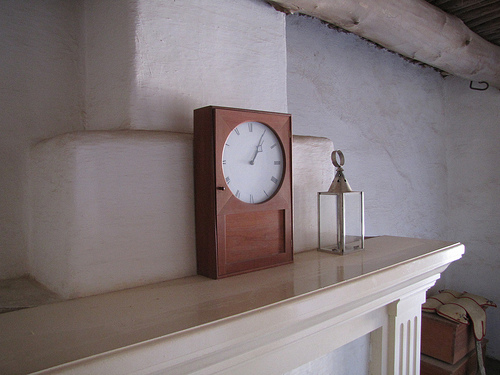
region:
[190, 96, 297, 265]
the clock sitting on the mantle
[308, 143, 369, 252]
a tiny little decoration by the clock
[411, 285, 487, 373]
some boes in the corner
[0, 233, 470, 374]
the mantle of the fireplace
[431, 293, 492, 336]
some fabric on top of the box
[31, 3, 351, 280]
a part of the chimney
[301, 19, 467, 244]
the wall of the house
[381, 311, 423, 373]
a column next to the fireplace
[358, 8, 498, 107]
a log near the ceiling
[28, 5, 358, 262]
part of the chimney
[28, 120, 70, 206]
Part of a white wall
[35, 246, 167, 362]
Part of a white wall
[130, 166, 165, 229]
Part of a white wall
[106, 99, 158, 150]
Part of a white wall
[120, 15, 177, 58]
Part of a white wall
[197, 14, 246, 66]
Part of a white wall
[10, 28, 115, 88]
Part of a white wall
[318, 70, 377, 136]
Part of a white wall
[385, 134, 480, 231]
Part of a white wall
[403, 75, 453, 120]
Part of a white wall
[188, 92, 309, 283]
a clock is white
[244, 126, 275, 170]
handles of clock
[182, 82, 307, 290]
a clock on brown frame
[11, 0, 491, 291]
a white wall behind a clock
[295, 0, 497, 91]
a log on a roof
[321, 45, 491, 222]
wall is color white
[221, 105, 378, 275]
a silver thing on side a clock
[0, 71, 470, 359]
a clock on side counter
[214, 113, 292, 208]
background of clock is white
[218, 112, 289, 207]
handles of clock are black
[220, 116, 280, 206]
A clock on the cabinet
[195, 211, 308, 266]
A wooden cabinet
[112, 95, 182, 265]
A wall in the building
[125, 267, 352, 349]
A chimney in the room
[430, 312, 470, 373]
Boxes in the photo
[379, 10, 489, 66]
Ceiling in the photo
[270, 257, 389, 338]
Wooden surface in the photo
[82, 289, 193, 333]
Smooth wooden edge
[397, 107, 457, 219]
A concrete wall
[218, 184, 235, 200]
A door handle in the photo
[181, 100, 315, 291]
SMALL WOODEN CLOCK ON MANTLE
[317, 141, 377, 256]
SMALL METAL BOX ON MANTLE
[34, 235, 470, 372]
MANTLE OF FIRE PLACE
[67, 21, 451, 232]
WHITE CONCRETE WALL IN ROOM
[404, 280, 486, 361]
BOX ON RIGHT WITH MATS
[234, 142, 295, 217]
ROMAN NUMERALS ON CLOCK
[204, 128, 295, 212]
WHITE FACE OF WOODEN CLOCK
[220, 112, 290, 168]
BLACK ARMS OF CLOCK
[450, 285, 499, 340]
YELLOW AND RED MATS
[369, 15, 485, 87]
LOG OVERHEAD ON CEILING